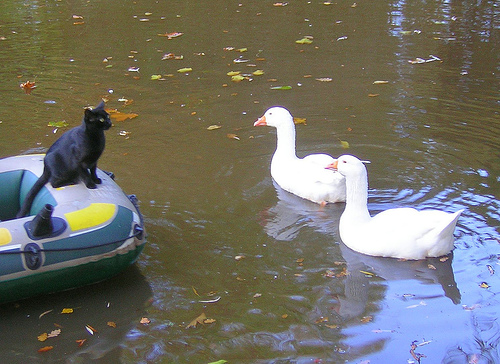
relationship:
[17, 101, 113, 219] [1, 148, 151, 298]
cat on top of boat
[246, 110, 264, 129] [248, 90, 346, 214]
beak attached to duck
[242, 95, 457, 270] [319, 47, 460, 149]
ducks are inside pond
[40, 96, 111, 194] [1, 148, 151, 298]
cat on top of boat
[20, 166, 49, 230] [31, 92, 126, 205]
tail of cat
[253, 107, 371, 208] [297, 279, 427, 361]
duck in water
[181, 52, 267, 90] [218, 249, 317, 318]
leaf in water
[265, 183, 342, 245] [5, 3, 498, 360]
goose reflection in water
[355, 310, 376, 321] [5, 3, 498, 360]
leaf floating in water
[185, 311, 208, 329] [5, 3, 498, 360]
leaf floating in water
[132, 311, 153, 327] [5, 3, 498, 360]
leaf floating in water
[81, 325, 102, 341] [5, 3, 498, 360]
leaf floating in water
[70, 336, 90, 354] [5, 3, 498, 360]
leaf floating in water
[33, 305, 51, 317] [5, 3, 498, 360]
leaf floating in water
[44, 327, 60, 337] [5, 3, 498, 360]
leaf floating in water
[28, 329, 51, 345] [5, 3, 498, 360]
leaf floating in water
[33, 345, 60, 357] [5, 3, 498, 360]
leaf floating in water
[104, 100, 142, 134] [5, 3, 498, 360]
leaf floating in water